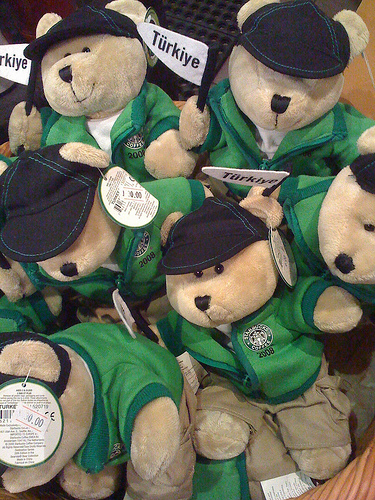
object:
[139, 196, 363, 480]
tan bear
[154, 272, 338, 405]
green jacket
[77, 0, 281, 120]
cages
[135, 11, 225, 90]
white flag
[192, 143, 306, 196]
white flag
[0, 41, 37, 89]
white flag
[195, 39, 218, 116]
black pole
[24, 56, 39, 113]
black pole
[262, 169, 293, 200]
black pole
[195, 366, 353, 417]
pants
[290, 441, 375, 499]
basket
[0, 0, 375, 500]
bears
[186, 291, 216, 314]
nose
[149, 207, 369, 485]
bear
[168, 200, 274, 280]
hat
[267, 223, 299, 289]
tag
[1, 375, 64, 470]
tag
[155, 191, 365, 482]
animal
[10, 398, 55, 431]
pricetag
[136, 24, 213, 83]
flag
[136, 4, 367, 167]
bear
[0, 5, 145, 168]
bear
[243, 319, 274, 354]
logo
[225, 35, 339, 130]
face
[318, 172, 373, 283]
face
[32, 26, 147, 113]
face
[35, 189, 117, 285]
face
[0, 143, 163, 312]
teddy bear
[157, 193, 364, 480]
teddy bear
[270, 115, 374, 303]
teddy bear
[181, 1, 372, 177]
teddy bear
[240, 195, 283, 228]
ear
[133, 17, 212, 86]
tag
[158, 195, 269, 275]
hat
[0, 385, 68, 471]
price tag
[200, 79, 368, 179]
jacket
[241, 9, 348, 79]
hat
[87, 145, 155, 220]
tag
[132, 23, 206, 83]
letters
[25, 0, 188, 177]
teddy bear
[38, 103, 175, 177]
jacket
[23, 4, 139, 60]
hat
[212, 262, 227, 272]
eyes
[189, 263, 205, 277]
eyes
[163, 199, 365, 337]
bear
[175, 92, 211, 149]
paws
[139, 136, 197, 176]
paws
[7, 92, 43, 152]
paws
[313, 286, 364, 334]
paws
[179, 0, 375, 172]
animal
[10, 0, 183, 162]
animal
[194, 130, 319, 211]
shirt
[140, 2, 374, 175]
bear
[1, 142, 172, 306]
bear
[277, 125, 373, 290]
bear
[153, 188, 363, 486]
bear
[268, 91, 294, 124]
nose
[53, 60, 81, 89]
nose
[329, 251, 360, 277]
nose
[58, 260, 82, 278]
nose